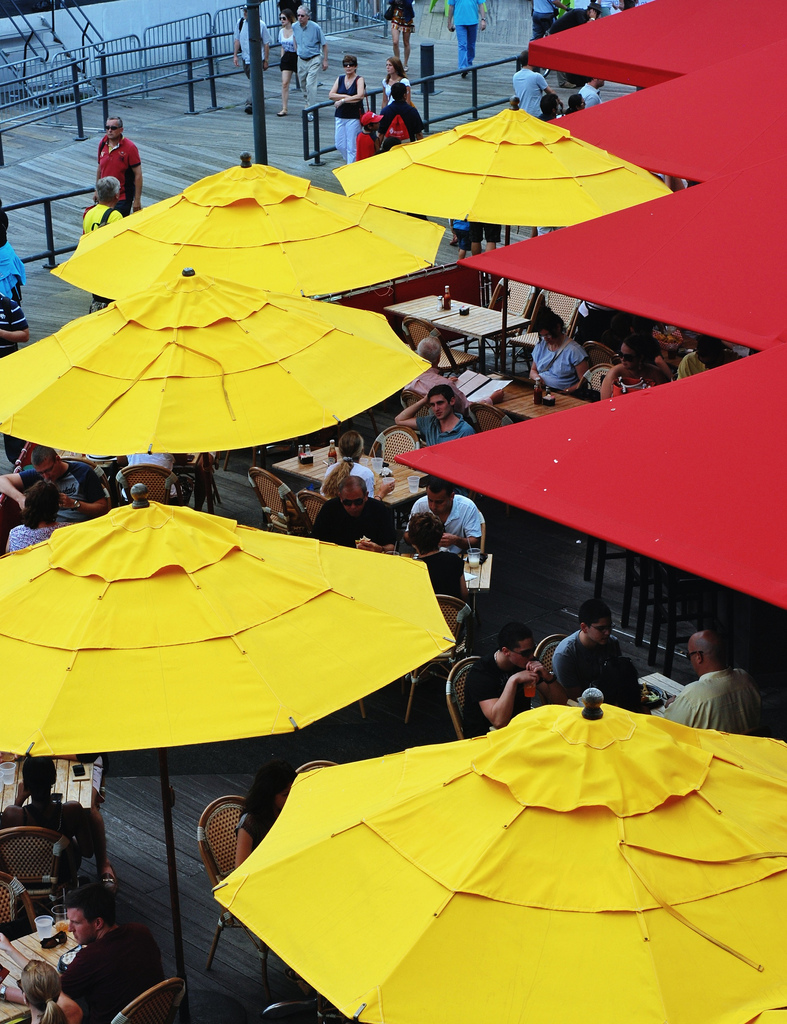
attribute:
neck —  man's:
[488, 648, 513, 665]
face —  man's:
[342, 486, 369, 518]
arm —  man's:
[389, 387, 433, 428]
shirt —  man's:
[316, 503, 401, 550]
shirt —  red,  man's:
[94, 134, 142, 201]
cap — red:
[356, 108, 386, 126]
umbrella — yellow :
[366, 117, 613, 237]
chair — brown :
[538, 642, 562, 692]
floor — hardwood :
[116, 807, 151, 879]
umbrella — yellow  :
[33, 510, 412, 674]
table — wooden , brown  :
[3, 928, 73, 965]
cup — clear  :
[23, 910, 63, 935]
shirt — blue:
[414, 407, 472, 445]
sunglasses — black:
[340, 490, 368, 511]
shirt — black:
[317, 497, 405, 549]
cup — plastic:
[517, 668, 541, 699]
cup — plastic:
[517, 665, 545, 707]